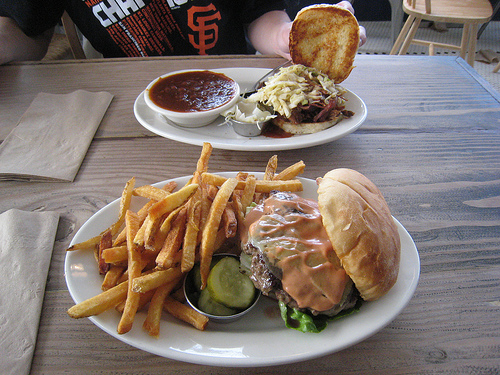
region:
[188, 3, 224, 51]
San Francisco Giants logo on shirt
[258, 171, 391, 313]
Hamburger on white plate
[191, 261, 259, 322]
Pickles in metal cup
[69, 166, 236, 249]
French fries on white plate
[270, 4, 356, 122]
Pulled pork sandwich with top opened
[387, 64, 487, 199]
Wooden table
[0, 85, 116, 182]
Brown napkin on wooden table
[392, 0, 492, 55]
Oak color Windsor chair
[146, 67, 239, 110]
White bowl with beans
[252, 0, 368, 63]
Hand holding top of sandwich bun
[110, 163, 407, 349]
large burger with fries and pickles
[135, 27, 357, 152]
barbecue sandwich with cole slaw and Chili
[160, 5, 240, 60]
San Francisco Giant's logo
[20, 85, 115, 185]
a brown paper napkin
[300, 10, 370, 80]
toasted bun for barbecue sandwich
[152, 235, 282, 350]
pickle slices on the side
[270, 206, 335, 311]
thousand island dressing as a condiment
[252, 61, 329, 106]
cole slaw as a topping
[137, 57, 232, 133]
small bowl of chili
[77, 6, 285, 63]
San Francisco Giants t-shirt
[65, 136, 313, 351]
A side order of french fries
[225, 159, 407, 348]
A burger with an open bun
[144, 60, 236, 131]
A cup of dipping sauce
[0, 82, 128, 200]
A folded napkin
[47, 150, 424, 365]
A plate with a burger and fries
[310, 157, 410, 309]
A hamburger bun top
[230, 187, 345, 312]
A peach colored condiment sauce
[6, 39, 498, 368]
A table with two plates of food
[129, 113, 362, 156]
A white plate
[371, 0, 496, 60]
An empty wooden chair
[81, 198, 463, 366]
French fries and cheeseburger on the plate.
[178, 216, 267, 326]
Pickles sit in between the fries and cheeseburger.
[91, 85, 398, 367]
Two plates of food on the table.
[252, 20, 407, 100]
A person holding a hamburger bun.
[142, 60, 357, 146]
A cup of chili and pastrami sandwich on the plate.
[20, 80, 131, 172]
A napkin next to the plate of food.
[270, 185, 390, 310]
The burger has cheese on it.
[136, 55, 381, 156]
The plate has a bowl of chilli.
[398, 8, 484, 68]
A wooden stool sit across from the table.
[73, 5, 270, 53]
A person wearing a black shirt with writing.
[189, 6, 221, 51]
San Francisco giants logo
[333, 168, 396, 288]
top of a hamburger bun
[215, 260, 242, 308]
pickles on the plate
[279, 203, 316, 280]
orange sauce on the burger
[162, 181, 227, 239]
golden french fries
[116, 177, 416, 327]
a white plate with a hamburger and fries on it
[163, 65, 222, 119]
some red sauce in a plate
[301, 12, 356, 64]
it is the top end of a hamburger bun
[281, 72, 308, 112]
onions on the burger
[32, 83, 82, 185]
a paper napkin